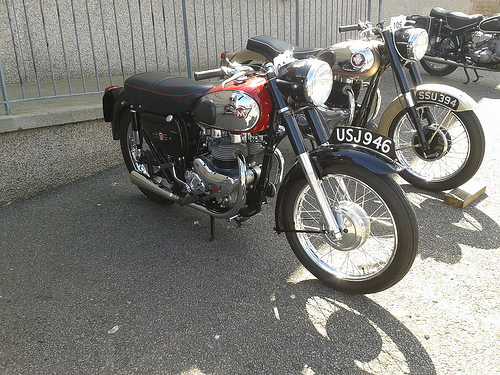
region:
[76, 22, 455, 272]
bikes on the street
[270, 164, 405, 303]
front tire of bike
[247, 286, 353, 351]
shadow on the ground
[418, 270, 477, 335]
light hitting the ground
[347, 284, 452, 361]
light and shadow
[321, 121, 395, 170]
number on the bike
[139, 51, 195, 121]
black seat on the bike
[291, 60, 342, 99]
light on the bike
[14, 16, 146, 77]
gate behind the bikes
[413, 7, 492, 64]
bike in the background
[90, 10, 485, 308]
three parked motorcycles on asphalt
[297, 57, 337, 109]
headlight on front of motorcycle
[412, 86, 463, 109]
letters and numbers on fender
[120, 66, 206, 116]
black seat on bike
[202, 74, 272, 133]
red and chrome gas tank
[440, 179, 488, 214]
wood block under tire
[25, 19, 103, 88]
metal rods in railing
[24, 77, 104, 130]
cement on top of ramp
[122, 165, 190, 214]
chrome exhaust pipe on bike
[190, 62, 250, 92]
brake and handle on handlebar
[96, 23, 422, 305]
a red and black motorcycle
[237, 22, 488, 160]
a gold and black motorcycle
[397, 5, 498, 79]
a black motorcycle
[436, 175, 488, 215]
a piece of 2x4 blocking a motorcycle wheel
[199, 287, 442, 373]
the shadow of a motorcycle on the ground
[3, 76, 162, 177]
a concrete ramp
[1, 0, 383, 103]
a metal railing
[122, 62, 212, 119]
the padded black seat of a motorcycle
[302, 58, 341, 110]
the headlight of a motorcycle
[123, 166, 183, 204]
the exhaust pipe of a motorcycle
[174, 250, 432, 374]
shadow of motorcycle on ground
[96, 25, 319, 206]
motorcycle is red and black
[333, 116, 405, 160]
white letters and numbers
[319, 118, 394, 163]
words spell usj946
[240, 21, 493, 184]
motorcycle is gold colored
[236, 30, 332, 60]
the seat is black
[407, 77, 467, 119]
words spell ssu394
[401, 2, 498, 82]
the motorcycle is black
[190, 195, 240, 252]
kick stand is down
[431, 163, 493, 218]
yellow object in front of motorcycle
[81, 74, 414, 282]
the bike has tires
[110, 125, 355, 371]
the bike has tires